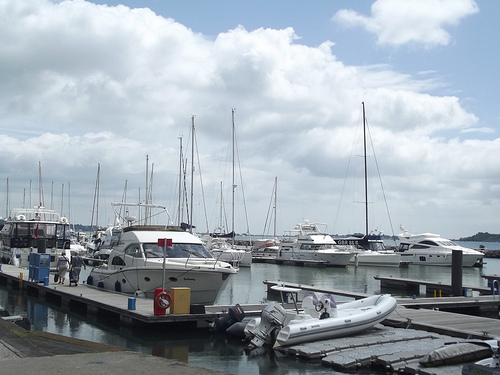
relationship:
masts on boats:
[101, 109, 277, 193] [77, 213, 271, 297]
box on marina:
[174, 277, 203, 312] [0, 264, 500, 375]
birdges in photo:
[82, 297, 162, 325] [26, 7, 434, 336]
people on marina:
[43, 242, 93, 278] [0, 264, 500, 375]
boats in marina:
[77, 213, 271, 297] [25, 235, 225, 350]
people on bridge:
[43, 242, 93, 278] [2, 263, 335, 353]